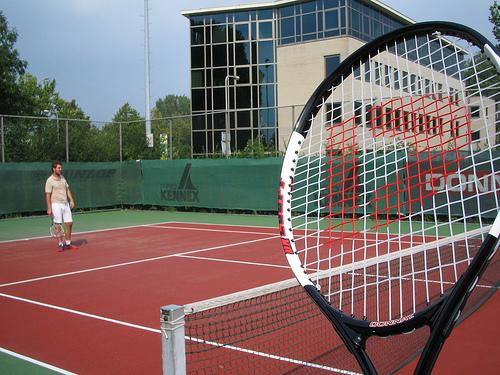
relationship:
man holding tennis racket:
[36, 156, 87, 253] [49, 222, 69, 239]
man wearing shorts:
[36, 156, 87, 253] [55, 210, 72, 220]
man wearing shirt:
[36, 156, 87, 253] [48, 182, 67, 201]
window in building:
[213, 45, 228, 65] [191, 8, 474, 142]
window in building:
[233, 111, 257, 130] [191, 8, 474, 142]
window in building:
[278, 18, 294, 38] [191, 8, 474, 142]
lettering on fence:
[422, 169, 499, 198] [145, 161, 271, 212]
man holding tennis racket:
[36, 156, 87, 253] [281, 29, 499, 361]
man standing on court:
[36, 156, 87, 253] [5, 225, 281, 330]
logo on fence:
[157, 158, 212, 212] [145, 161, 271, 212]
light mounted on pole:
[226, 72, 241, 81] [220, 82, 232, 155]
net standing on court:
[159, 286, 311, 373] [5, 225, 281, 330]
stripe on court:
[186, 252, 279, 271] [5, 225, 281, 330]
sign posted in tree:
[160, 135, 172, 161] [160, 102, 187, 133]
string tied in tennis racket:
[305, 184, 309, 206] [281, 29, 499, 361]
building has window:
[191, 8, 474, 142] [213, 45, 228, 65]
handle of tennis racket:
[423, 341, 446, 374] [281, 29, 499, 361]